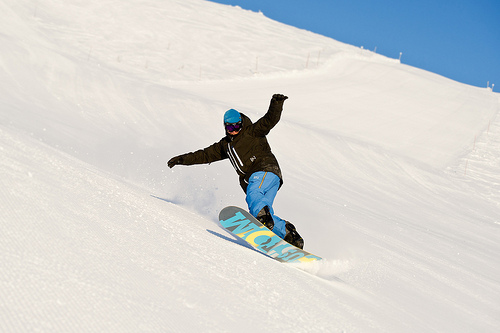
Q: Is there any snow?
A: Yes, there is snow.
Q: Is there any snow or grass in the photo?
A: Yes, there is snow.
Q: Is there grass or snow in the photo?
A: Yes, there is snow.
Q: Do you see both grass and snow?
A: No, there is snow but no grass.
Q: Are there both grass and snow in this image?
A: No, there is snow but no grass.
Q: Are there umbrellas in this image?
A: No, there are no umbrellas.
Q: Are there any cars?
A: No, there are no cars.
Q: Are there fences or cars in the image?
A: No, there are no cars or fences.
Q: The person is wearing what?
A: The person is wearing a coat.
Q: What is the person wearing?
A: The person is wearing a coat.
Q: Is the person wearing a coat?
A: Yes, the person is wearing a coat.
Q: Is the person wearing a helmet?
A: No, the person is wearing a coat.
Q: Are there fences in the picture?
A: No, there are no fences.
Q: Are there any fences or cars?
A: No, there are no fences or cars.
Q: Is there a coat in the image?
A: Yes, there is a coat.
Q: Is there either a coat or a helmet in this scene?
A: Yes, there is a coat.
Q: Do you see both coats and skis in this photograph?
A: Yes, there are both a coat and skis.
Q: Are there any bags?
A: No, there are no bags.